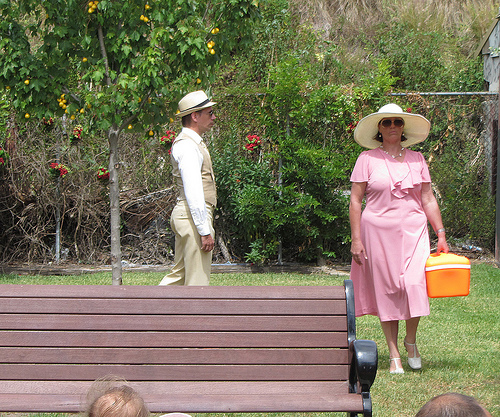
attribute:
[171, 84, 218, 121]
hat — tan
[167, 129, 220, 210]
vest — tan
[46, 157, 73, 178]
flowers — red 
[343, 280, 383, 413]
support — Black , metal 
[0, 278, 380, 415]
bench — Black , wooden , wood 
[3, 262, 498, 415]
grass — green, short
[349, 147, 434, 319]
dress — pink 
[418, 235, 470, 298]
container — orange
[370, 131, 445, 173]
bead necklace — white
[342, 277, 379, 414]
rails — metal 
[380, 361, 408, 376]
shoe — white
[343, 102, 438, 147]
hat — wide 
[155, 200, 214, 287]
pants — tan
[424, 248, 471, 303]
lunchbox — orange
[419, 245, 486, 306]
container — orange 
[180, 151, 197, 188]
shirt — white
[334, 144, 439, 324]
dress — pink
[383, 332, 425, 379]
sandal — tan , strap 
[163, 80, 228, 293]
man — walking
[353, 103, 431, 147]
brim hat — wide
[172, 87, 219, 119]
hat — white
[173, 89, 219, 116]
fedora — tan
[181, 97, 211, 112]
stripe — black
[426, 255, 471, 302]
plastic box — orange, white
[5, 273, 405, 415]
bench — empty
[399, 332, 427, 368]
shoe — white 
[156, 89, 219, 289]
man —  tan , walking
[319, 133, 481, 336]
dress — pink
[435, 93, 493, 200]
fence — chain link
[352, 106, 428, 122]
hat — tan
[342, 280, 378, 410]
arm rest — metal 